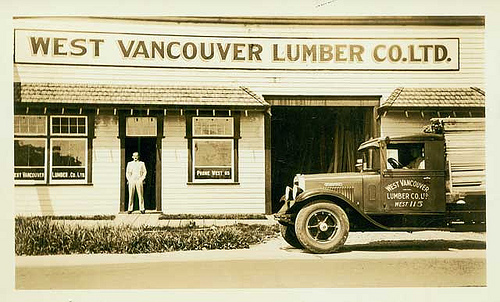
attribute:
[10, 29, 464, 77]
sign — large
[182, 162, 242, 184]
sign — dark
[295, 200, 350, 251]
tire — black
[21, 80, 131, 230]
window — glass, paneled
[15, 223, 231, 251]
plants — small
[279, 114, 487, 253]
lorry — black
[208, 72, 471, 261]
lorry — old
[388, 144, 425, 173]
window — open